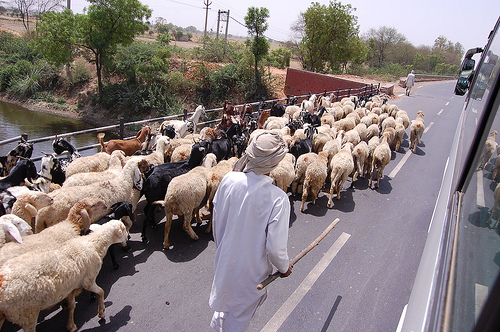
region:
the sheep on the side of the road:
[18, 73, 418, 314]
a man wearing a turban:
[212, 91, 302, 206]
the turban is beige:
[200, 107, 297, 179]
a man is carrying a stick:
[188, 160, 393, 325]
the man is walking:
[212, 125, 359, 327]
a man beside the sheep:
[170, 95, 344, 330]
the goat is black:
[142, 121, 242, 240]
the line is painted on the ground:
[387, 124, 433, 220]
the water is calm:
[12, 97, 131, 164]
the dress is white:
[185, 150, 285, 323]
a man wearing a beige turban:
[217, 126, 285, 326]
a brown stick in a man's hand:
[263, 210, 337, 290]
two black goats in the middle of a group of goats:
[148, 123, 245, 191]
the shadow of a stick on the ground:
[321, 287, 347, 328]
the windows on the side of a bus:
[456, 42, 498, 328]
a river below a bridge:
[1, 93, 87, 141]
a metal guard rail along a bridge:
[68, 75, 368, 145]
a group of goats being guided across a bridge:
[3, 99, 383, 311]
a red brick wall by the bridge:
[285, 61, 372, 101]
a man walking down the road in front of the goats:
[398, 63, 420, 96]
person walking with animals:
[46, 75, 428, 303]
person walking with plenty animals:
[18, 67, 442, 290]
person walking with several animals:
[51, 69, 434, 303]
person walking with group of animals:
[29, 56, 426, 290]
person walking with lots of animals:
[31, 67, 436, 314]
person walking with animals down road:
[25, 42, 445, 298]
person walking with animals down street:
[57, 61, 427, 303]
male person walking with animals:
[25, 50, 434, 298]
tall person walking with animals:
[6, 48, 435, 318]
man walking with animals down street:
[25, 38, 436, 304]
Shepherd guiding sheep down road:
[206, 131, 296, 329]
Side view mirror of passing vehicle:
[453, 43, 483, 101]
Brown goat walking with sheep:
[97, 123, 155, 152]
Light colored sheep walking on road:
[3, 188, 133, 328]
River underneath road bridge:
[1, 62, 102, 125]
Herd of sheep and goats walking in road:
[289, 97, 394, 176]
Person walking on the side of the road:
[401, 68, 417, 96]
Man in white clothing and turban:
[209, 130, 296, 330]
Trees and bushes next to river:
[1, 23, 100, 114]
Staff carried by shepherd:
[248, 216, 344, 291]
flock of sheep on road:
[5, 110, 217, 327]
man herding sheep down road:
[219, 130, 309, 327]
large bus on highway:
[415, 4, 497, 329]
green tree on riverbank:
[39, 0, 147, 106]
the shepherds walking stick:
[245, 201, 364, 297]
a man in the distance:
[402, 66, 420, 100]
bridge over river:
[0, 67, 438, 202]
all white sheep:
[322, 107, 427, 201]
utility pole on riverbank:
[182, 1, 237, 60]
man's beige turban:
[240, 128, 287, 185]